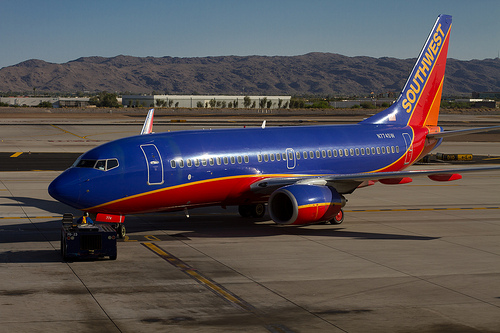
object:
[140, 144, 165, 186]
door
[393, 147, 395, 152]
window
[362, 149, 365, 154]
window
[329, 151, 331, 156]
window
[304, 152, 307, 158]
window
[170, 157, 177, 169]
window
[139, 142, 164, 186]
cabin door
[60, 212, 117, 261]
vehicle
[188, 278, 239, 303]
line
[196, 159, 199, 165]
window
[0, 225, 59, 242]
shadow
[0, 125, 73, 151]
tarmac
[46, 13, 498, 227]
plane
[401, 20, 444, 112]
word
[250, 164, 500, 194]
wing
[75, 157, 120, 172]
cockpit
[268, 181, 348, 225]
engine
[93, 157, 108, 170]
window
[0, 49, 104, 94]
mountains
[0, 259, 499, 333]
runway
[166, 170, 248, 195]
stripe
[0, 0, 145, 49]
sky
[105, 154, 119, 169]
window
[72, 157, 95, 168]
window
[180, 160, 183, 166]
window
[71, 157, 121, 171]
cockpit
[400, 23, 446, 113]
logo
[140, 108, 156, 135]
wing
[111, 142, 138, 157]
paint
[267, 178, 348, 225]
right propeller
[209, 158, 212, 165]
windows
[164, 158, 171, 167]
pilot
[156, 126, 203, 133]
floor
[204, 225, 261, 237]
shadow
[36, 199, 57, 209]
shadow